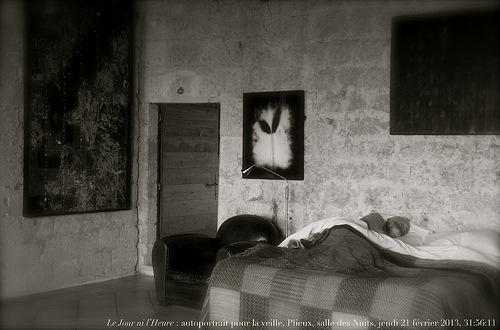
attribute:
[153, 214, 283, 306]
chair — over 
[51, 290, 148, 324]
tiles — white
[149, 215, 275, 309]
chair — black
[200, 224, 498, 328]
blanket — checkered pattern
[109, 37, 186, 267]
wall — side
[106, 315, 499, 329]
description — typed 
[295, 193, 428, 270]
man — sleeping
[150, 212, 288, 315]
chair — dark, color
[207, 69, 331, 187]
picture — black , white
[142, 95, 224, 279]
door way — another room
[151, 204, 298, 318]
chair — dark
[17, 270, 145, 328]
floor — tiled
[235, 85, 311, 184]
picture — black, white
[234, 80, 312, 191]
frame — picture 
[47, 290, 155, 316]
floor — tile, stone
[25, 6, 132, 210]
painting — large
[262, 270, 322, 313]
print — block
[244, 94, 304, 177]
painting — black, background